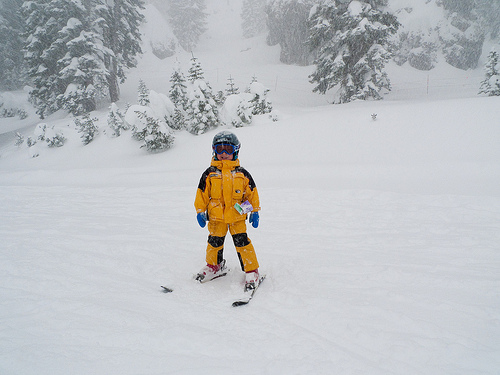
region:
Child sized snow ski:
[229, 272, 258, 305]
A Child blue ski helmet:
[204, 131, 244, 156]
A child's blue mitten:
[246, 213, 261, 228]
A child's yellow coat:
[195, 160, 262, 217]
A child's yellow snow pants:
[200, 221, 252, 281]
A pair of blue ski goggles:
[205, 144, 242, 156]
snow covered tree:
[131, 100, 175, 151]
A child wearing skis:
[180, 117, 272, 299]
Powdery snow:
[301, 124, 407, 343]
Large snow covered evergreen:
[26, 0, 218, 4]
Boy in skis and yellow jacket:
[149, 116, 284, 328]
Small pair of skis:
[153, 245, 286, 325]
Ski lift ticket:
[231, 194, 266, 221]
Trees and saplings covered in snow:
[2, 0, 497, 127]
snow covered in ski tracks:
[0, 165, 487, 372]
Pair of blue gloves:
[186, 210, 271, 230]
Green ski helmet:
[197, 127, 250, 153]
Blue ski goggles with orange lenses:
[206, 141, 241, 157]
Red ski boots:
[188, 257, 285, 287]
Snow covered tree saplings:
[163, 52, 234, 137]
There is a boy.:
[144, 113, 306, 313]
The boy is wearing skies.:
[142, 251, 284, 316]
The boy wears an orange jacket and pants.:
[179, 124, 281, 268]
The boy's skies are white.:
[151, 266, 281, 311]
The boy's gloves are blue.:
[191, 206, 212, 231]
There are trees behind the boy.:
[2, 2, 494, 144]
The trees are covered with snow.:
[2, 2, 497, 128]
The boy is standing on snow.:
[141, 108, 289, 315]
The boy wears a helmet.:
[207, 127, 245, 166]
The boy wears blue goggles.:
[208, 139, 241, 155]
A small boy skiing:
[141, 109, 300, 339]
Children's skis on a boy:
[146, 248, 292, 318]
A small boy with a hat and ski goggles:
[201, 130, 258, 170]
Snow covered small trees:
[130, 52, 278, 127]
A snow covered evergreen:
[20, 32, 148, 109]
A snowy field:
[313, 147, 457, 336]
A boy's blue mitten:
[183, 200, 218, 230]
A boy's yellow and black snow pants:
[203, 217, 264, 272]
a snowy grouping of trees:
[13, 35, 498, 125]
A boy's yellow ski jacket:
[191, 165, 268, 227]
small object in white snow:
[358, 106, 415, 133]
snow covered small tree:
[113, 102, 175, 159]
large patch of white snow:
[302, 134, 484, 314]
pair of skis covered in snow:
[150, 269, 280, 305]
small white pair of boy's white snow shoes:
[194, 260, 274, 287]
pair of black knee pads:
[202, 231, 266, 251]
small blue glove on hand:
[192, 210, 215, 225]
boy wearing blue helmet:
[203, 126, 249, 153]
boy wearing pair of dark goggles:
[192, 141, 254, 161]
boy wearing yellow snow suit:
[168, 116, 290, 310]